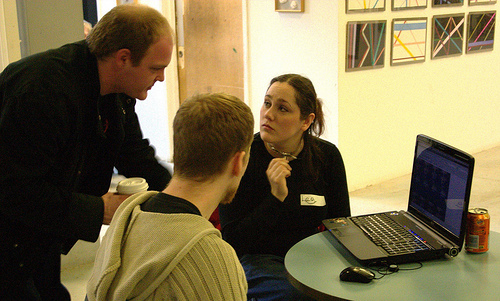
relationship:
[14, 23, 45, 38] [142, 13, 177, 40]
plate on table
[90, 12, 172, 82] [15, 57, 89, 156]
man in coat